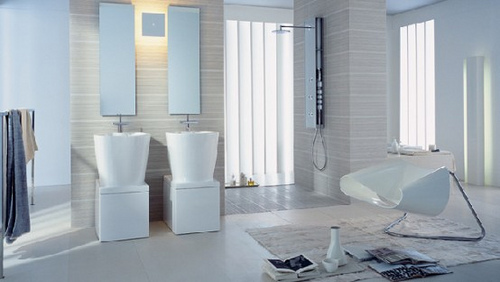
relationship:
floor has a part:
[118, 167, 423, 269] [259, 213, 269, 222]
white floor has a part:
[200, 235, 234, 270] [230, 227, 253, 255]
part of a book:
[272, 269, 290, 276] [261, 253, 321, 281]